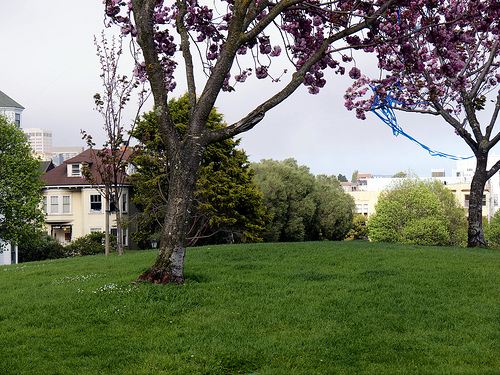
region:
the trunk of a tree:
[137, 146, 211, 281]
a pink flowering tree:
[101, 1, 358, 103]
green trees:
[247, 152, 353, 244]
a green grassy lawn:
[0, 238, 498, 373]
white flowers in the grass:
[90, 277, 136, 297]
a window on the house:
[86, 187, 101, 214]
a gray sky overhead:
[0, 0, 499, 185]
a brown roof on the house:
[35, 145, 145, 188]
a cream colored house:
[33, 185, 139, 255]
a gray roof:
[0, 89, 25, 110]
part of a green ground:
[285, 239, 336, 304]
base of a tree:
[138, 245, 190, 280]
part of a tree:
[461, 220, 483, 263]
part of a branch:
[228, 91, 278, 156]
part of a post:
[87, 218, 128, 273]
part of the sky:
[308, 116, 352, 171]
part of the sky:
[323, 108, 372, 155]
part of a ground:
[264, 305, 321, 369]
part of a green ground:
[304, 240, 333, 269]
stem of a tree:
[168, 200, 215, 255]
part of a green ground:
[336, 270, 386, 333]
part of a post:
[99, 227, 106, 242]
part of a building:
[356, 185, 367, 201]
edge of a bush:
[288, 157, 344, 234]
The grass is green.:
[204, 270, 324, 336]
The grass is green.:
[319, 301, 409, 366]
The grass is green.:
[274, 291, 364, 356]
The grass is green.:
[293, 306, 383, 372]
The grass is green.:
[283, 283, 422, 362]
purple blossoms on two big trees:
[101, 0, 496, 285]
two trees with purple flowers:
[100, 0, 495, 285]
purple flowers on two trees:
[100, 1, 496, 286]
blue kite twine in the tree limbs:
[369, 7, 474, 160]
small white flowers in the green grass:
[52, 270, 136, 315]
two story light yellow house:
[37, 148, 150, 253]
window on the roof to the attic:
[69, 163, 81, 175]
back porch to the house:
[50, 224, 73, 245]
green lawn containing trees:
[0, 240, 498, 373]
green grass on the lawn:
[207, 247, 454, 357]